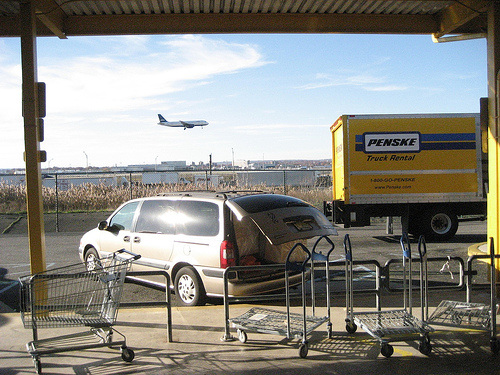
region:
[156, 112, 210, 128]
In flight passenger airplane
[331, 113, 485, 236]
The back half of a yellow rental truck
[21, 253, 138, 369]
silver shopping cart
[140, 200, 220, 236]
Sun glare on a minivan window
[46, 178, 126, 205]
Field full of tall brown grass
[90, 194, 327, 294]
A gold colored minivan with the back hatch open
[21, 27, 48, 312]
Tall yellow pole for structure security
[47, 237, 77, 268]
Asphalt parking lot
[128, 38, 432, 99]
Partly cloudy sky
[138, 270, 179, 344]
metal railing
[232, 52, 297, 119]
this is the sky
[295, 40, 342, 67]
the sky is blue in color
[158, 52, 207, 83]
these are the clouds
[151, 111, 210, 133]
this is a jet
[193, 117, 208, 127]
the jet is white in color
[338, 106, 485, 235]
this is a lorry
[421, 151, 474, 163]
the lorry is yellow in color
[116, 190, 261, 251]
this is a car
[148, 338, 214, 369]
this is a floor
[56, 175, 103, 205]
this is the fence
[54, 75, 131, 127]
white clouds covering the sky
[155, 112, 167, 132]
blue tail on plane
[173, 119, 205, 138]
wings on the plane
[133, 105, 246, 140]
plane in the air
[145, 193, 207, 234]
large shine on the van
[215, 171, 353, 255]
cargo door open on the van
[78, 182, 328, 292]
van backed up to the ramp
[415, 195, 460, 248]
black and white wheels on truck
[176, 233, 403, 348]
shopping carts on the side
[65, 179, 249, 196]
tall brown grass in the field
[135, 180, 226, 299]
this is a car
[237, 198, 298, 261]
the trunk is open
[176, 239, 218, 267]
the car is grey in color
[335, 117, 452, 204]
this is a lorry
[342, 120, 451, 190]
the lorry is yellow in color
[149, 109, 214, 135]
this is a plane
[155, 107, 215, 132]
the plane is on air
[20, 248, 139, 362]
this is a carriage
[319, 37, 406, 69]
the sky is blue in color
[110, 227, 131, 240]
the door is closed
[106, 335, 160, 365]
black wheel on shopping cart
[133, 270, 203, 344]
gray handle on front of building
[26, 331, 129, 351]
rack under the cart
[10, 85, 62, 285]
large yellow post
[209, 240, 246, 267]
red light at back of van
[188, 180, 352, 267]
open door at rear of van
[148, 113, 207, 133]
large plane in the air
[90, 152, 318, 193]
long flat white building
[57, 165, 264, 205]
long clear fence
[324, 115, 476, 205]
large blue and yellow truck